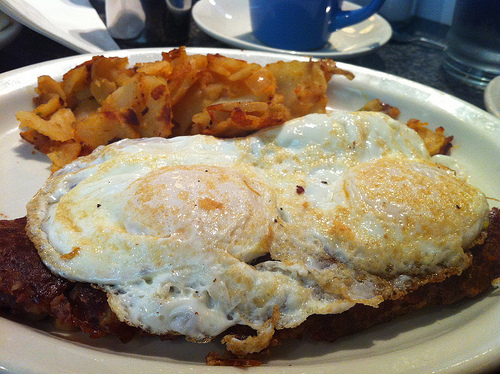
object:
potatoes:
[13, 45, 353, 173]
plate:
[0, 47, 500, 374]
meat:
[0, 212, 500, 344]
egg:
[25, 110, 493, 360]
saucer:
[189, 1, 394, 57]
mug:
[251, 0, 392, 45]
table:
[0, 1, 500, 113]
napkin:
[1, 0, 122, 56]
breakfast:
[0, 47, 499, 369]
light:
[355, 19, 381, 41]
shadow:
[48, 298, 468, 362]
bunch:
[104, 51, 210, 132]